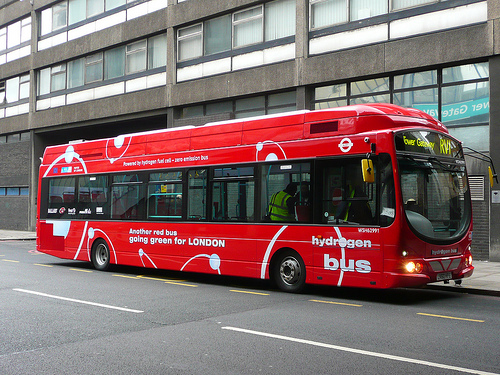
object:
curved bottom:
[413, 229, 469, 247]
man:
[266, 182, 299, 223]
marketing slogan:
[129, 228, 225, 247]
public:
[178, 118, 254, 277]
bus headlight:
[405, 260, 423, 274]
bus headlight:
[465, 255, 473, 265]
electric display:
[403, 136, 451, 155]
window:
[0, 71, 29, 105]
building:
[0, 0, 497, 262]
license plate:
[437, 272, 453, 281]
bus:
[35, 103, 500, 293]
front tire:
[271, 248, 306, 293]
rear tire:
[91, 238, 110, 270]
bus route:
[403, 136, 451, 155]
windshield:
[395, 127, 472, 240]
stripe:
[220, 325, 500, 375]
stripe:
[13, 287, 145, 314]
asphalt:
[0, 239, 500, 375]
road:
[2, 240, 500, 375]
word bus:
[323, 254, 371, 274]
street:
[0, 239, 498, 373]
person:
[329, 182, 376, 226]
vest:
[265, 190, 294, 221]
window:
[106, 169, 146, 221]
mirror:
[361, 159, 374, 182]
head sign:
[403, 136, 451, 155]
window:
[77, 174, 109, 221]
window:
[147, 168, 184, 222]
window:
[186, 168, 208, 221]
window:
[210, 161, 256, 222]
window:
[314, 153, 397, 229]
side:
[35, 109, 398, 293]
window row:
[37, 151, 396, 227]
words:
[129, 228, 178, 236]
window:
[47, 175, 77, 220]